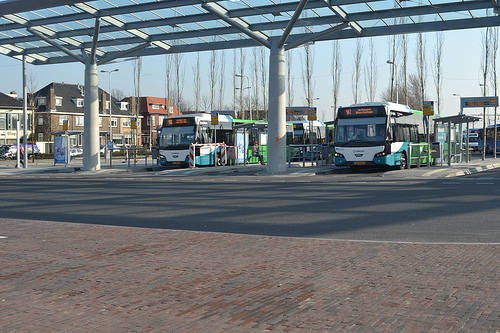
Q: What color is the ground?
A: Gray.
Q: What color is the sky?
A: Blue.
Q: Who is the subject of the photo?
A: Buses.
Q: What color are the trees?
A: Brown.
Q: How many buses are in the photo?
A: 2.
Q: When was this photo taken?
A: During the day.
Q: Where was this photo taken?
A: At a bus depot.